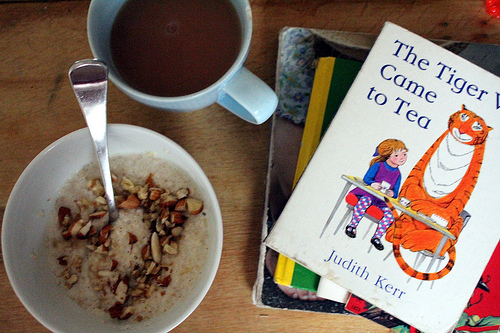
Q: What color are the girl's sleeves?
A: Blue.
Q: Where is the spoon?
A: Bowl.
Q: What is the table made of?
A: Wood.